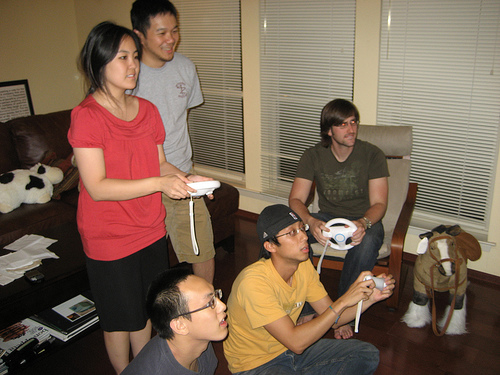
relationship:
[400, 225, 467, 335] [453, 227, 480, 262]
horse has saddle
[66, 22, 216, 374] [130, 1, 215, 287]
woman next to man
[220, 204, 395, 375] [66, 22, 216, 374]
guy in front of woman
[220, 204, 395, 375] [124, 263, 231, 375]
guy next to guy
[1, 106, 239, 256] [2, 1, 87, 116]
couch against wall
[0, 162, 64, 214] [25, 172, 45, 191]
cow has spot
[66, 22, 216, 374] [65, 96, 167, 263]
woman wearing top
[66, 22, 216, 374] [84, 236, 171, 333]
woman wearing skirt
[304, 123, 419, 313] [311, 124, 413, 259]
chair has cushion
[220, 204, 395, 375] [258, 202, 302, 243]
guy wearing cap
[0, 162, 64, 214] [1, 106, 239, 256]
cow on couch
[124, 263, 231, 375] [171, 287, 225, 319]
guy wearing glasses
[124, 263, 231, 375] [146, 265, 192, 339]
guy has hair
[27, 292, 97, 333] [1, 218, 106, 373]
book on coffee table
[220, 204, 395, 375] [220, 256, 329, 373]
guy wearing tshirt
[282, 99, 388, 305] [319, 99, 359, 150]
man has hair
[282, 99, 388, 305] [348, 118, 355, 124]
man has eye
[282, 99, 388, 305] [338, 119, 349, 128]
man has eye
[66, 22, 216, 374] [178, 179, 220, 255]
woman holding controller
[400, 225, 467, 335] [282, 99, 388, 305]
horse next to man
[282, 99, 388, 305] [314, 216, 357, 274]
man holding steering wheel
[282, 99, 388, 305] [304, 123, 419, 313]
man sitting in chair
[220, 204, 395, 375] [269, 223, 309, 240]
guy wearing glasses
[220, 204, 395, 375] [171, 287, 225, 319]
guy wearing glasses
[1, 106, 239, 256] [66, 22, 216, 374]
couch behind woman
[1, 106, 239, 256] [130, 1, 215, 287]
couch behind man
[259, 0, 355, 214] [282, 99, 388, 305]
blinds behind man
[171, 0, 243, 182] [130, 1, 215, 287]
blinds behind man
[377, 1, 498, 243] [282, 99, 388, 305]
blinds behind man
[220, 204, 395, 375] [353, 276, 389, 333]
guy holding controller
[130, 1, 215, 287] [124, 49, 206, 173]
man wearing tshirt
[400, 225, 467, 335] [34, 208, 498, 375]
horse on floor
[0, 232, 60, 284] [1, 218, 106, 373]
papers on coffee table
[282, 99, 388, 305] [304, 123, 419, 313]
man in chair